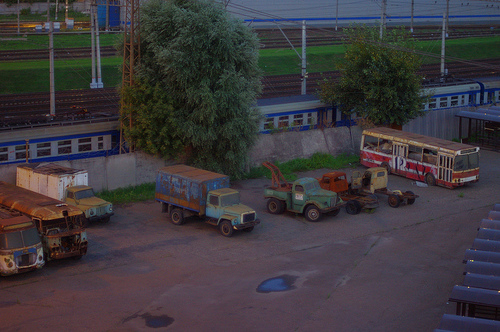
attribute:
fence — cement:
[304, 119, 460, 169]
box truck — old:
[151, 165, 258, 237]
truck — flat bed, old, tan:
[351, 165, 419, 208]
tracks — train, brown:
[1, 80, 125, 126]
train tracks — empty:
[2, 24, 499, 127]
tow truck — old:
[261, 158, 338, 221]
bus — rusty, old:
[0, 212, 56, 279]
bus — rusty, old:
[4, 182, 90, 267]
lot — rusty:
[122, 228, 272, 314]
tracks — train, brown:
[0, 24, 497, 59]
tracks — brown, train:
[10, 57, 490, 132]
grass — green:
[5, 33, 495, 88]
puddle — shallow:
[254, 272, 297, 293]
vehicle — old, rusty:
[316, 164, 376, 213]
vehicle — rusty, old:
[37, 192, 85, 264]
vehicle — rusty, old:
[308, 157, 415, 216]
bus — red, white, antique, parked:
[361, 127, 481, 184]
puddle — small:
[254, 268, 307, 298]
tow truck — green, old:
[264, 174, 340, 227]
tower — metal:
[116, 1, 147, 156]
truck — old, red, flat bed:
[314, 168, 382, 219]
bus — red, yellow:
[359, 125, 481, 189]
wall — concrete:
[43, 153, 293, 189]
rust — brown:
[174, 178, 189, 198]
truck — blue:
[152, 163, 260, 236]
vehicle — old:
[25, 191, 87, 263]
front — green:
[219, 183, 249, 241]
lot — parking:
[176, 203, 327, 304]